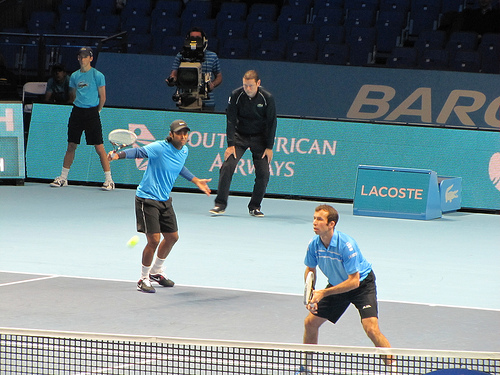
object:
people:
[104, 71, 400, 374]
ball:
[129, 238, 138, 246]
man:
[106, 120, 213, 294]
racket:
[108, 129, 137, 156]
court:
[1, 177, 500, 374]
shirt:
[121, 139, 197, 204]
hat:
[170, 118, 191, 134]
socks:
[139, 258, 166, 280]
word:
[345, 84, 499, 128]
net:
[0, 329, 500, 375]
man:
[209, 69, 281, 219]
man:
[165, 29, 222, 112]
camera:
[168, 38, 212, 111]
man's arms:
[119, 144, 151, 159]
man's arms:
[92, 70, 106, 108]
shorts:
[133, 197, 177, 233]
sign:
[184, 129, 338, 181]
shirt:
[302, 234, 374, 286]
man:
[305, 204, 378, 374]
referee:
[205, 70, 277, 218]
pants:
[214, 146, 273, 211]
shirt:
[223, 86, 279, 149]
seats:
[3, 1, 500, 77]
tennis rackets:
[303, 271, 316, 305]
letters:
[359, 184, 423, 200]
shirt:
[172, 51, 223, 107]